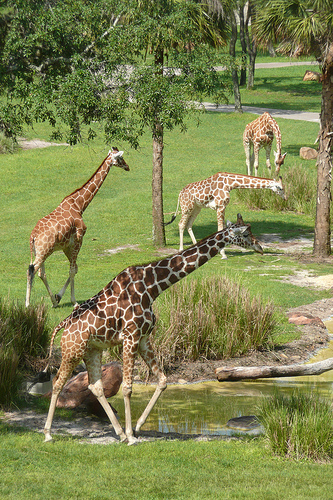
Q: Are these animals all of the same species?
A: Yes, all the animals are giraffes.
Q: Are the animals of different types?
A: No, all the animals are giraffes.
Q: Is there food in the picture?
A: Yes, there is food.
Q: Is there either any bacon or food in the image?
A: Yes, there is food.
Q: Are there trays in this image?
A: No, there are no trays.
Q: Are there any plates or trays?
A: No, there are no trays or plates.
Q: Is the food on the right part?
A: Yes, the food is on the right of the image.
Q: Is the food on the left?
A: No, the food is on the right of the image.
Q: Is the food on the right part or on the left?
A: The food is on the right of the image.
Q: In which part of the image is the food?
A: The food is on the right of the image.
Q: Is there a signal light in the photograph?
A: No, there are no traffic lights.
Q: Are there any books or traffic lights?
A: No, there are no traffic lights or books.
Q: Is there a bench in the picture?
A: No, there are no benches.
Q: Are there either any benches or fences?
A: No, there are no benches or fences.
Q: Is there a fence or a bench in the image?
A: No, there are no benches or fences.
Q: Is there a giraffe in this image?
A: Yes, there is a giraffe.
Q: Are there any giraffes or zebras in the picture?
A: Yes, there is a giraffe.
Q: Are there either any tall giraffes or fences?
A: Yes, there is a tall giraffe.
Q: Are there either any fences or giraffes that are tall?
A: Yes, the giraffe is tall.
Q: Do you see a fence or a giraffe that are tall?
A: Yes, the giraffe is tall.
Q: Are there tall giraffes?
A: Yes, there is a tall giraffe.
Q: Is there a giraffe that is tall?
A: Yes, there is a giraffe that is tall.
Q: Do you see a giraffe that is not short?
A: Yes, there is a tall giraffe.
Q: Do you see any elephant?
A: No, there are no elephants.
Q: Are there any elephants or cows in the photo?
A: No, there are no elephants or cows.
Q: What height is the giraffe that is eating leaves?
A: The giraffe is tall.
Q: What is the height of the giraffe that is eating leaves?
A: The giraffe is tall.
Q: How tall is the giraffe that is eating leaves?
A: The giraffe is tall.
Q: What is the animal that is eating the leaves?
A: The animal is a giraffe.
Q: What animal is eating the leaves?
A: The animal is a giraffe.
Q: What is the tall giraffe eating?
A: The giraffe is eating leaves.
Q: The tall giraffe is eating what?
A: The giraffe is eating leaves.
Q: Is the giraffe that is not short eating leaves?
A: Yes, the giraffe is eating leaves.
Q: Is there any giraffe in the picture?
A: Yes, there is a giraffe.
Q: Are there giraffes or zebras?
A: Yes, there is a giraffe.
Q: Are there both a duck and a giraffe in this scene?
A: No, there is a giraffe but no ducks.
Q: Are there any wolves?
A: No, there are no wolves.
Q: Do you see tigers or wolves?
A: No, there are no wolves or tigers.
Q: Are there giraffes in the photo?
A: Yes, there is a giraffe.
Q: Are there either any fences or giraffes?
A: Yes, there is a giraffe.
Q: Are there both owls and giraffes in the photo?
A: No, there is a giraffe but no owls.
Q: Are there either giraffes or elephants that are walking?
A: Yes, the giraffe is walking.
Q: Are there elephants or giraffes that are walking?
A: Yes, the giraffe is walking.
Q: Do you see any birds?
A: No, there are no birds.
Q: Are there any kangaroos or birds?
A: No, there are no birds or kangaroos.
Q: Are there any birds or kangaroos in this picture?
A: No, there are no birds or kangaroos.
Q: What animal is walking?
A: The animal is a giraffe.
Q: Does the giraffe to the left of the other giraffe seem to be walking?
A: Yes, the giraffe is walking.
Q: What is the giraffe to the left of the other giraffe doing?
A: The giraffe is walking.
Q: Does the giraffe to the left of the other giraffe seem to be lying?
A: No, the giraffe is walking.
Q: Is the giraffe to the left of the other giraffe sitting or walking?
A: The giraffe is walking.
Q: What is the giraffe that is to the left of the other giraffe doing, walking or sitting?
A: The giraffe is walking.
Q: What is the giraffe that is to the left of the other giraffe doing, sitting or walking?
A: The giraffe is walking.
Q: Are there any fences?
A: No, there are no fences.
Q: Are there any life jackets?
A: No, there are no life jackets.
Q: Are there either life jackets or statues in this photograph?
A: No, there are no life jackets or statues.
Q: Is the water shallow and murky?
A: Yes, the water is shallow and murky.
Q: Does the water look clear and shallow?
A: No, the water is shallow but murky.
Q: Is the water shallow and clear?
A: No, the water is shallow but murky.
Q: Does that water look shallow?
A: Yes, the water is shallow.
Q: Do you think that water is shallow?
A: Yes, the water is shallow.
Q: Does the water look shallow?
A: Yes, the water is shallow.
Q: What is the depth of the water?
A: The water is shallow.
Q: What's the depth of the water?
A: The water is shallow.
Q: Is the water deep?
A: No, the water is shallow.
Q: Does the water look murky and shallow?
A: Yes, the water is murky and shallow.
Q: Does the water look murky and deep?
A: No, the water is murky but shallow.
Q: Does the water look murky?
A: Yes, the water is murky.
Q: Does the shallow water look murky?
A: Yes, the water is murky.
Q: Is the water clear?
A: No, the water is murky.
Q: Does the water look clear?
A: No, the water is murky.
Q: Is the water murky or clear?
A: The water is murky.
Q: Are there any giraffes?
A: Yes, there is a giraffe.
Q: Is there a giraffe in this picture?
A: Yes, there is a giraffe.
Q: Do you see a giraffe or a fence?
A: Yes, there is a giraffe.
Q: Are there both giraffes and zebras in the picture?
A: No, there is a giraffe but no zebras.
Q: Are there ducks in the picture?
A: No, there are no ducks.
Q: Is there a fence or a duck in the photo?
A: No, there are no ducks or fences.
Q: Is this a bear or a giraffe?
A: This is a giraffe.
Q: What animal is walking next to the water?
A: The giraffe is walking next to the water.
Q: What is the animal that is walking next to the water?
A: The animal is a giraffe.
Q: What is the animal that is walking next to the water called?
A: The animal is a giraffe.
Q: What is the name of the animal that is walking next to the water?
A: The animal is a giraffe.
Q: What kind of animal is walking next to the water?
A: The animal is a giraffe.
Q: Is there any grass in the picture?
A: Yes, there is grass.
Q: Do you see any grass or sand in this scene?
A: Yes, there is grass.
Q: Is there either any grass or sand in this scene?
A: Yes, there is grass.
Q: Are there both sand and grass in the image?
A: No, there is grass but no sand.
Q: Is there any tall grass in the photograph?
A: Yes, there is tall grass.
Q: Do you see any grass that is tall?
A: Yes, there is grass that is tall.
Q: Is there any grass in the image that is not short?
A: Yes, there is tall grass.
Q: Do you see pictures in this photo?
A: No, there are no pictures.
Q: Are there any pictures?
A: No, there are no pictures.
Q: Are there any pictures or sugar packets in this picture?
A: No, there are no pictures or sugar packets.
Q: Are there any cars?
A: No, there are no cars.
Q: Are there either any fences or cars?
A: No, there are no cars or fences.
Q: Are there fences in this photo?
A: No, there are no fences.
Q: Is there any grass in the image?
A: Yes, there is grass.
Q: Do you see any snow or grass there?
A: Yes, there is grass.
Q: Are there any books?
A: No, there are no books.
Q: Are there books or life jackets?
A: No, there are no books or life jackets.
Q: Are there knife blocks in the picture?
A: No, there are no knife blocks.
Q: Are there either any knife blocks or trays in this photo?
A: No, there are no knife blocks or trays.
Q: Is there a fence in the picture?
A: No, there are no fences.